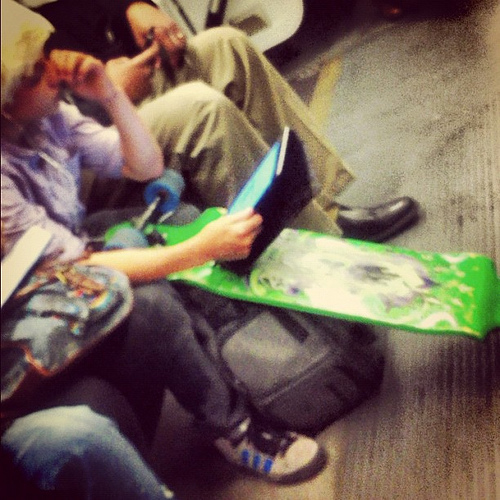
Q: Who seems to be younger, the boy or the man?
A: The boy is younger than the man.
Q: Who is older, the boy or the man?
A: The man is older than the boy.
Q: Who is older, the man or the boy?
A: The man is older than the boy.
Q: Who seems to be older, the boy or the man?
A: The man is older than the boy.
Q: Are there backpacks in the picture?
A: Yes, there is a backpack.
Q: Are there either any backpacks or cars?
A: Yes, there is a backpack.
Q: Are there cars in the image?
A: No, there are no cars.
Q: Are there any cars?
A: No, there are no cars.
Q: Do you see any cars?
A: No, there are no cars.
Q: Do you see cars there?
A: No, there are no cars.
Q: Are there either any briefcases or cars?
A: No, there are no cars or briefcases.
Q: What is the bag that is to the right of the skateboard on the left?
A: The bag is a backpack.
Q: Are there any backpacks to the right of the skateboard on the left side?
A: Yes, there is a backpack to the right of the skateboard.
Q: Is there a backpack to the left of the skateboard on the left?
A: No, the backpack is to the right of the skateboard.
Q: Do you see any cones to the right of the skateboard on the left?
A: No, there is a backpack to the right of the skateboard.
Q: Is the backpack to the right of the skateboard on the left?
A: Yes, the backpack is to the right of the skateboard.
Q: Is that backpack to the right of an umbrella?
A: No, the backpack is to the right of the skateboard.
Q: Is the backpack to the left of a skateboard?
A: No, the backpack is to the right of a skateboard.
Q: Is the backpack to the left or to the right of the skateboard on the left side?
A: The backpack is to the right of the skateboard.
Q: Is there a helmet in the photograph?
A: No, there are no helmets.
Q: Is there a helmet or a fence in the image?
A: No, there are no helmets or fences.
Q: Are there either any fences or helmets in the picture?
A: No, there are no helmets or fences.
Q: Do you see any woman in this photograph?
A: No, there are no women.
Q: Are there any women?
A: No, there are no women.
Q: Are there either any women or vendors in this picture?
A: No, there are no women or vendors.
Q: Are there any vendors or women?
A: No, there are no women or vendors.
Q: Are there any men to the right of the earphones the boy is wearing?
A: Yes, there is a man to the right of the earphones.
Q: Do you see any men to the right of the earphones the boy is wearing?
A: Yes, there is a man to the right of the earphones.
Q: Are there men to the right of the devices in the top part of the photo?
A: Yes, there is a man to the right of the earphones.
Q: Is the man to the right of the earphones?
A: Yes, the man is to the right of the earphones.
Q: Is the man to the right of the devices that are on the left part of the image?
A: Yes, the man is to the right of the earphones.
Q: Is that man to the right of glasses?
A: No, the man is to the right of the earphones.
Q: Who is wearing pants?
A: The man is wearing pants.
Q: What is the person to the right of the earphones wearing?
A: The man is wearing trousers.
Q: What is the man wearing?
A: The man is wearing trousers.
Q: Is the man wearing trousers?
A: Yes, the man is wearing trousers.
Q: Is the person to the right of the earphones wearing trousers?
A: Yes, the man is wearing trousers.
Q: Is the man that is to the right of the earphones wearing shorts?
A: No, the man is wearing trousers.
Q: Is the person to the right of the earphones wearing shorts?
A: No, the man is wearing trousers.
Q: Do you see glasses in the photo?
A: No, there are no glasses.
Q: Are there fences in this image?
A: No, there are no fences.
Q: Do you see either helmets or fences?
A: No, there are no fences or helmets.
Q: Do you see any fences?
A: No, there are no fences.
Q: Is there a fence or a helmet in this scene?
A: No, there are no fences or helmets.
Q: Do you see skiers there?
A: No, there are no skiers.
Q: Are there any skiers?
A: No, there are no skiers.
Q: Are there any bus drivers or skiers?
A: No, there are no skiers or bus drivers.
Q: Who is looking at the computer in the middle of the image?
A: The boy is looking at the computer.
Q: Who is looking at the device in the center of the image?
A: The boy is looking at the computer.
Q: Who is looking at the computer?
A: The boy is looking at the computer.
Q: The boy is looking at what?
A: The boy is looking at the computer.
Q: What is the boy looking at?
A: The boy is looking at the computer.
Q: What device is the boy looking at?
A: The boy is looking at the computer.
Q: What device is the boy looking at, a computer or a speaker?
A: The boy is looking at a computer.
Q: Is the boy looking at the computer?
A: Yes, the boy is looking at the computer.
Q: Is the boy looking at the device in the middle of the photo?
A: Yes, the boy is looking at the computer.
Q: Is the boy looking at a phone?
A: No, the boy is looking at the computer.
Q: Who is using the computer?
A: The boy is using the computer.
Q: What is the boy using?
A: The boy is using a computer.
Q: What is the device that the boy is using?
A: The device is a computer.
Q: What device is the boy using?
A: The boy is using a computer.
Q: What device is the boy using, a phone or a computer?
A: The boy is using a computer.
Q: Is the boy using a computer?
A: Yes, the boy is using a computer.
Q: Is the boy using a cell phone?
A: No, the boy is using a computer.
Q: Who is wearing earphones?
A: The boy is wearing earphones.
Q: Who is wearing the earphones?
A: The boy is wearing earphones.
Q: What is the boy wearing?
A: The boy is wearing earphones.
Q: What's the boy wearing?
A: The boy is wearing earphones.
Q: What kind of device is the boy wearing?
A: The boy is wearing earphones.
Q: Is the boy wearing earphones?
A: Yes, the boy is wearing earphones.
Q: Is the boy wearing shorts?
A: No, the boy is wearing earphones.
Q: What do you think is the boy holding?
A: The boy is holding the skateboard.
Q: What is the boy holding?
A: The boy is holding the skateboard.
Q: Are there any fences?
A: No, there are no fences.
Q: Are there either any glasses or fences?
A: No, there are no fences or glasses.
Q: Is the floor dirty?
A: Yes, the floor is dirty.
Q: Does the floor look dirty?
A: Yes, the floor is dirty.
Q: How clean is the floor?
A: The floor is dirty.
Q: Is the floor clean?
A: No, the floor is dirty.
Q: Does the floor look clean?
A: No, the floor is dirty.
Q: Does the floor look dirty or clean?
A: The floor is dirty.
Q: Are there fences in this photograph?
A: No, there are no fences.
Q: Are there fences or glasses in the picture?
A: No, there are no fences or glasses.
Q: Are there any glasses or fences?
A: No, there are no fences or glasses.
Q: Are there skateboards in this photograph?
A: Yes, there is a skateboard.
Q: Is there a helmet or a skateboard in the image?
A: Yes, there is a skateboard.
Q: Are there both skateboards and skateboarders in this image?
A: No, there is a skateboard but no skateboarders.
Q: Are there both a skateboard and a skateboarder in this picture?
A: No, there is a skateboard but no skateboarders.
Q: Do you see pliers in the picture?
A: No, there are no pliers.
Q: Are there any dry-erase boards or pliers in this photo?
A: No, there are no pliers or dry-erase boards.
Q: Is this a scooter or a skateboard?
A: This is a skateboard.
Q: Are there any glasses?
A: No, there are no glasses.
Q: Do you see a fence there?
A: No, there are no fences.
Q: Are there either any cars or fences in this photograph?
A: No, there are no fences or cars.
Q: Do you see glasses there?
A: No, there are no glasses.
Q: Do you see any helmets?
A: No, there are no helmets.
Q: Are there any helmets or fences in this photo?
A: No, there are no helmets or fences.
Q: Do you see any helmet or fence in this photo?
A: No, there are no helmets or fences.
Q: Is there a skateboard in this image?
A: Yes, there is a skateboard.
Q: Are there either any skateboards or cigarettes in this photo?
A: Yes, there is a skateboard.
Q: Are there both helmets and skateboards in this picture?
A: No, there is a skateboard but no helmets.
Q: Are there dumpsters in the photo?
A: No, there are no dumpsters.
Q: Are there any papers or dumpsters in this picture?
A: No, there are no dumpsters or papers.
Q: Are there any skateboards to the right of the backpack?
A: No, the skateboard is to the left of the backpack.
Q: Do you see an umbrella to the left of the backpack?
A: No, there is a skateboard to the left of the backpack.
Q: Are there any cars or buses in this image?
A: No, there are no cars or buses.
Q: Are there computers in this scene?
A: Yes, there is a computer.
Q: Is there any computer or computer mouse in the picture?
A: Yes, there is a computer.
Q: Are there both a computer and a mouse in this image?
A: No, there is a computer but no computer mice.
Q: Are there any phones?
A: No, there are no phones.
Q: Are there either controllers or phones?
A: No, there are no phones or controllers.